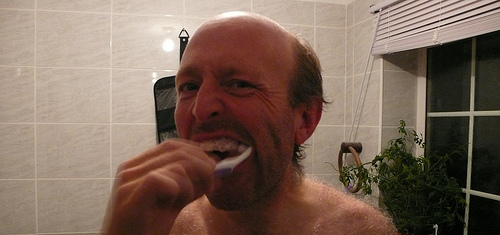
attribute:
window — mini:
[383, 5, 499, 221]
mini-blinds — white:
[375, 3, 498, 45]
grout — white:
[17, 63, 71, 128]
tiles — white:
[33, 10, 115, 65]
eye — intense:
[177, 79, 197, 92]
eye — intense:
[229, 76, 253, 89]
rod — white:
[351, 53, 377, 148]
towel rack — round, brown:
[341, 143, 364, 190]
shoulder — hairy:
[290, 161, 399, 233]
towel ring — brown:
[335, 140, 367, 193]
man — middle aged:
[95, 12, 397, 232]